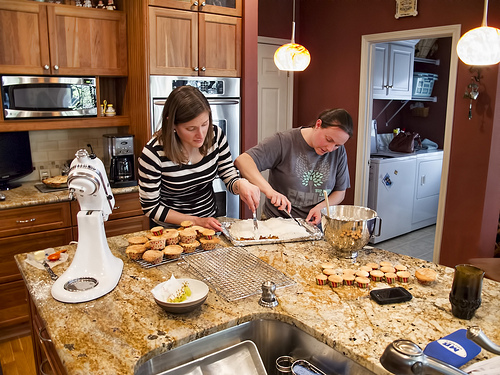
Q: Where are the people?
A: The kitchen.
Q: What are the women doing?
A: Cutting.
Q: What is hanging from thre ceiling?
A: Lights.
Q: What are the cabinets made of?
A: Wood.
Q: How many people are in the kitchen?
A: Two.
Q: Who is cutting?
A: The women.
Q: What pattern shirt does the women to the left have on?
A: Stripes.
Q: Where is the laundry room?
A: To the right.